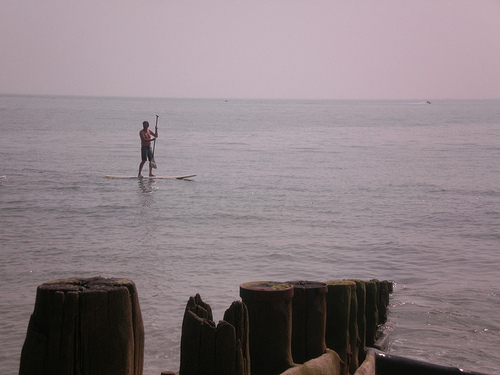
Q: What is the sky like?
A: Foggy and grey.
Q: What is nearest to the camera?
A: Wood post.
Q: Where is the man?
A: On the surfboard.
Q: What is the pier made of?
A: Posts of wood.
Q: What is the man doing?
A: Rowing.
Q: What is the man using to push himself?
A: A pole.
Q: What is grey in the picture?
A: The sea.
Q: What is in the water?
A: A man.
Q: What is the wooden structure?
A: Pier.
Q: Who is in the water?
A: Surfer.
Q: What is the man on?
A: Surfboard.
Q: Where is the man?
A: Ocean.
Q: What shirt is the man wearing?
A: Shirtless.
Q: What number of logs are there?
A: 9.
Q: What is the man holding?
A: Oar.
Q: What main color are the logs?
A: Brown.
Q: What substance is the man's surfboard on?
A: Water.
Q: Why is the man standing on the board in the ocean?
A: Surfing.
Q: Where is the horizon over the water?
A: Over the water.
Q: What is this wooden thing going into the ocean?
A: A pier.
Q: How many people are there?
A: One.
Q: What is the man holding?
A: A stick.